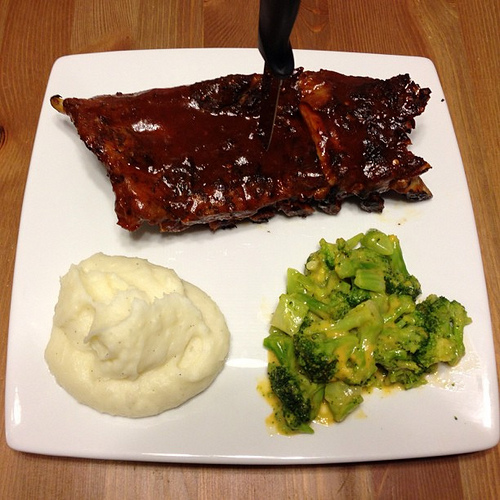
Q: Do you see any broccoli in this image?
A: Yes, there is broccoli.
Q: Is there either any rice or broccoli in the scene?
A: Yes, there is broccoli.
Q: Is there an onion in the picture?
A: No, there are no onions.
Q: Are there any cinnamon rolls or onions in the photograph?
A: No, there are no onions or cinnamon rolls.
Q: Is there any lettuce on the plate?
A: No, there is broccoli on the plate.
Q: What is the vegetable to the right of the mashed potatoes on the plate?
A: The vegetable is broccoli.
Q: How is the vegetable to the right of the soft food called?
A: The vegetable is broccoli.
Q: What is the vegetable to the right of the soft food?
A: The vegetable is broccoli.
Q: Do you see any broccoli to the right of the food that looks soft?
A: Yes, there is broccoli to the right of the mashed potatoes.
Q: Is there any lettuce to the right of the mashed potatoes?
A: No, there is broccoli to the right of the mashed potatoes.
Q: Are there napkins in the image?
A: No, there are no napkins.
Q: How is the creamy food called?
A: The food is mashed potatoes.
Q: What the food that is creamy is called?
A: The food is mashed potatoes.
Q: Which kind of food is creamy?
A: The food is mashed potatoes.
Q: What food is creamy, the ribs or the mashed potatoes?
A: The mashed potatoes is creamy.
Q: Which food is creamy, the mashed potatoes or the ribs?
A: The mashed potatoes is creamy.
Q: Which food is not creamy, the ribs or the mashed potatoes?
A: The ribs is not creamy.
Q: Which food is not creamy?
A: The food is ribs.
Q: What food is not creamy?
A: The food is ribs.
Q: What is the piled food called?
A: The food is mashed potatoes.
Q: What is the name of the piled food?
A: The food is mashed potatoes.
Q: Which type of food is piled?
A: The food is mashed potatoes.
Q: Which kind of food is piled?
A: The food is mashed potatoes.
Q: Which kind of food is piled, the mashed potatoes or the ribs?
A: The mashed potatoes is piled.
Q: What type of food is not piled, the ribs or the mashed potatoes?
A: The ribs is not piled.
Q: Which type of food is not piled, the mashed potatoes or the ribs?
A: The ribs is not piled.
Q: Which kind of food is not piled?
A: The food is ribs.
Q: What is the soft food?
A: The food is mashed potatoes.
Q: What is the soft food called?
A: The food is mashed potatoes.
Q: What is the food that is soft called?
A: The food is mashed potatoes.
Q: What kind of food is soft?
A: The food is mashed potatoes.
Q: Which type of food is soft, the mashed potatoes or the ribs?
A: The mashed potatoes is soft.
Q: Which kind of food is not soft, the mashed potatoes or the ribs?
A: The ribs is not soft.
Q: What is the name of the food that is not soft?
A: The food is ribs.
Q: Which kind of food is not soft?
A: The food is ribs.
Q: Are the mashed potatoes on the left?
A: Yes, the mashed potatoes are on the left of the image.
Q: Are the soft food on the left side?
A: Yes, the mashed potatoes are on the left of the image.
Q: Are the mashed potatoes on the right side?
A: No, the mashed potatoes are on the left of the image.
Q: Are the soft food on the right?
A: No, the mashed potatoes are on the left of the image.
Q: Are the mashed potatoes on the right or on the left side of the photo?
A: The mashed potatoes are on the left of the image.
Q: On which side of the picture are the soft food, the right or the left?
A: The mashed potatoes are on the left of the image.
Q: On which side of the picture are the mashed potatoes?
A: The mashed potatoes are on the left of the image.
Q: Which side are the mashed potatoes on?
A: The mashed potatoes are on the left of the image.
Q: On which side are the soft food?
A: The mashed potatoes are on the left of the image.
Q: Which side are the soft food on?
A: The mashed potatoes are on the left of the image.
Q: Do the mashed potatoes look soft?
A: Yes, the mashed potatoes are soft.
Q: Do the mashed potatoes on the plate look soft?
A: Yes, the mashed potatoes are soft.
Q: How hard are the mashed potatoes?
A: The mashed potatoes are soft.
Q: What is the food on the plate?
A: The food is mashed potatoes.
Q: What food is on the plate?
A: The food is mashed potatoes.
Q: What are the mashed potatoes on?
A: The mashed potatoes are on the plate.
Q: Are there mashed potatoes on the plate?
A: Yes, there are mashed potatoes on the plate.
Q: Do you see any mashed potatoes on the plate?
A: Yes, there are mashed potatoes on the plate.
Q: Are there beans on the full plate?
A: No, there are mashed potatoes on the plate.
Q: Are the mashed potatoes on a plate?
A: Yes, the mashed potatoes are on a plate.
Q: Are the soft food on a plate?
A: Yes, the mashed potatoes are on a plate.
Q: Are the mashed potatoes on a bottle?
A: No, the mashed potatoes are on a plate.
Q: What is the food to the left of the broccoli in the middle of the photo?
A: The food is mashed potatoes.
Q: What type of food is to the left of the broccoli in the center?
A: The food is mashed potatoes.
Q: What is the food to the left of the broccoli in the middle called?
A: The food is mashed potatoes.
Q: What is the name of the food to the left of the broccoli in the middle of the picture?
A: The food is mashed potatoes.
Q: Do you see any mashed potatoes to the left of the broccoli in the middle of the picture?
A: Yes, there are mashed potatoes to the left of the broccoli.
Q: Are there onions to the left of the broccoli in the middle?
A: No, there are mashed potatoes to the left of the broccoli.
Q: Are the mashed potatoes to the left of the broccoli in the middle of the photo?
A: Yes, the mashed potatoes are to the left of the broccoli.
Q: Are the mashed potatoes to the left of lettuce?
A: No, the mashed potatoes are to the left of the broccoli.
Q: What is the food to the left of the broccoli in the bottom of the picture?
A: The food is mashed potatoes.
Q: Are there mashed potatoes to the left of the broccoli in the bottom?
A: Yes, there are mashed potatoes to the left of the broccoli.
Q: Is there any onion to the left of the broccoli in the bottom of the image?
A: No, there are mashed potatoes to the left of the broccoli.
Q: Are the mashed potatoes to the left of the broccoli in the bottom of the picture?
A: Yes, the mashed potatoes are to the left of the broccoli.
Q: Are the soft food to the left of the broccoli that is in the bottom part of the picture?
A: Yes, the mashed potatoes are to the left of the broccoli.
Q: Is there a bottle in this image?
A: No, there are no bottles.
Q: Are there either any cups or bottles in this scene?
A: No, there are no bottles or cups.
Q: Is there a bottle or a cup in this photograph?
A: No, there are no bottles or cups.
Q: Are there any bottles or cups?
A: No, there are no bottles or cups.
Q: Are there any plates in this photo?
A: Yes, there is a plate.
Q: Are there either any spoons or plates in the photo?
A: Yes, there is a plate.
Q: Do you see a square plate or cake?
A: Yes, there is a square plate.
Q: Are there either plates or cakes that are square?
A: Yes, the plate is square.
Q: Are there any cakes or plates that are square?
A: Yes, the plate is square.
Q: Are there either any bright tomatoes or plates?
A: Yes, there is a bright plate.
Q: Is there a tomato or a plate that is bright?
A: Yes, the plate is bright.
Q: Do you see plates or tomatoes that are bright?
A: Yes, the plate is bright.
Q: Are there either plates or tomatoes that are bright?
A: Yes, the plate is bright.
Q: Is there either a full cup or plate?
A: Yes, there is a full plate.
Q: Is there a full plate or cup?
A: Yes, there is a full plate.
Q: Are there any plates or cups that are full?
A: Yes, the plate is full.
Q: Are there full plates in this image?
A: Yes, there is a full plate.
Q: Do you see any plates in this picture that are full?
A: Yes, there is a plate that is full.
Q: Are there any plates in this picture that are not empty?
A: Yes, there is an full plate.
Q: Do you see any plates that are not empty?
A: Yes, there is an full plate.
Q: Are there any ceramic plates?
A: Yes, there is a porcelain plate.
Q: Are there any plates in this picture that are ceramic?
A: Yes, there is a plate that is ceramic.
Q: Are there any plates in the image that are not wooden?
A: Yes, there is a ceramic plate.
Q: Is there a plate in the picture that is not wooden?
A: Yes, there is a ceramic plate.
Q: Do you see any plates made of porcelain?
A: Yes, there is a plate that is made of porcelain.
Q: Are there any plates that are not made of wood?
A: Yes, there is a plate that is made of porcelain.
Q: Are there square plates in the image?
A: Yes, there is a square plate.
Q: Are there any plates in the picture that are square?
A: Yes, there is a plate that is square.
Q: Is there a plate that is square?
A: Yes, there is a plate that is square.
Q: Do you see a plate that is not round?
A: Yes, there is a square plate.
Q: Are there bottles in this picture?
A: No, there are no bottles.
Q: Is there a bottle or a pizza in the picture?
A: No, there are no bottles or pizzas.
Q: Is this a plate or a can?
A: This is a plate.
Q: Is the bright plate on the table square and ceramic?
A: Yes, the plate is square and ceramic.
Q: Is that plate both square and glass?
A: No, the plate is square but ceramic.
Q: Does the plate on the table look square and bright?
A: Yes, the plate is square and bright.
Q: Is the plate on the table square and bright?
A: Yes, the plate is square and bright.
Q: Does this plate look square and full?
A: Yes, the plate is square and full.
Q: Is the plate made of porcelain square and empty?
A: No, the plate is square but full.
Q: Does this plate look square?
A: Yes, the plate is square.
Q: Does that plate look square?
A: Yes, the plate is square.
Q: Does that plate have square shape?
A: Yes, the plate is square.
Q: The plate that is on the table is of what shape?
A: The plate is square.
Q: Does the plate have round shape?
A: No, the plate is square.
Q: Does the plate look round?
A: No, the plate is square.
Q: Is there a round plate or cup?
A: No, there is a plate but it is square.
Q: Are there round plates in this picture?
A: No, there is a plate but it is square.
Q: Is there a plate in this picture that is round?
A: No, there is a plate but it is square.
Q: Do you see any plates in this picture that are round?
A: No, there is a plate but it is square.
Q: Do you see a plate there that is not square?
A: No, there is a plate but it is square.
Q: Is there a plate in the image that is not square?
A: No, there is a plate but it is square.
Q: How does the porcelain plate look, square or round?
A: The plate is square.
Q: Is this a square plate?
A: Yes, this is a square plate.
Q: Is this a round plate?
A: No, this is a square plate.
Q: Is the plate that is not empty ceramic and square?
A: Yes, the plate is ceramic and square.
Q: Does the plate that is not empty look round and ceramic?
A: No, the plate is ceramic but square.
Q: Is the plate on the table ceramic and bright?
A: Yes, the plate is ceramic and bright.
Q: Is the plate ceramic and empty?
A: No, the plate is ceramic but full.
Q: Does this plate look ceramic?
A: Yes, the plate is ceramic.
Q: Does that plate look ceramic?
A: Yes, the plate is ceramic.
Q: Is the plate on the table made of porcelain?
A: Yes, the plate is made of porcelain.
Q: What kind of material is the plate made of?
A: The plate is made of porcelain.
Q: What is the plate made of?
A: The plate is made of porcelain.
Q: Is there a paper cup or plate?
A: No, there is a plate but it is ceramic.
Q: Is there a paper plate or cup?
A: No, there is a plate but it is ceramic.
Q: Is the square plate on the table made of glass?
A: No, the plate is made of porcelain.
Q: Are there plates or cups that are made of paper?
A: No, there is a plate but it is made of porcelain.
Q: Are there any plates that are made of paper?
A: No, there is a plate but it is made of porcelain.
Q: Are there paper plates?
A: No, there is a plate but it is made of porcelain.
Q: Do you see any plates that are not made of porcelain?
A: No, there is a plate but it is made of porcelain.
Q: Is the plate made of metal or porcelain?
A: The plate is made of porcelain.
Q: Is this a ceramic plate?
A: Yes, this is a ceramic plate.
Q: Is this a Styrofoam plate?
A: No, this is a ceramic plate.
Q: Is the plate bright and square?
A: Yes, the plate is bright and square.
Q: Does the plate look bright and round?
A: No, the plate is bright but square.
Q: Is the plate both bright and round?
A: No, the plate is bright but square.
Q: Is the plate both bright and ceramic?
A: Yes, the plate is bright and ceramic.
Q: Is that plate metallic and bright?
A: No, the plate is bright but ceramic.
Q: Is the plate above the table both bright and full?
A: Yes, the plate is bright and full.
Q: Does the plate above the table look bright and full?
A: Yes, the plate is bright and full.